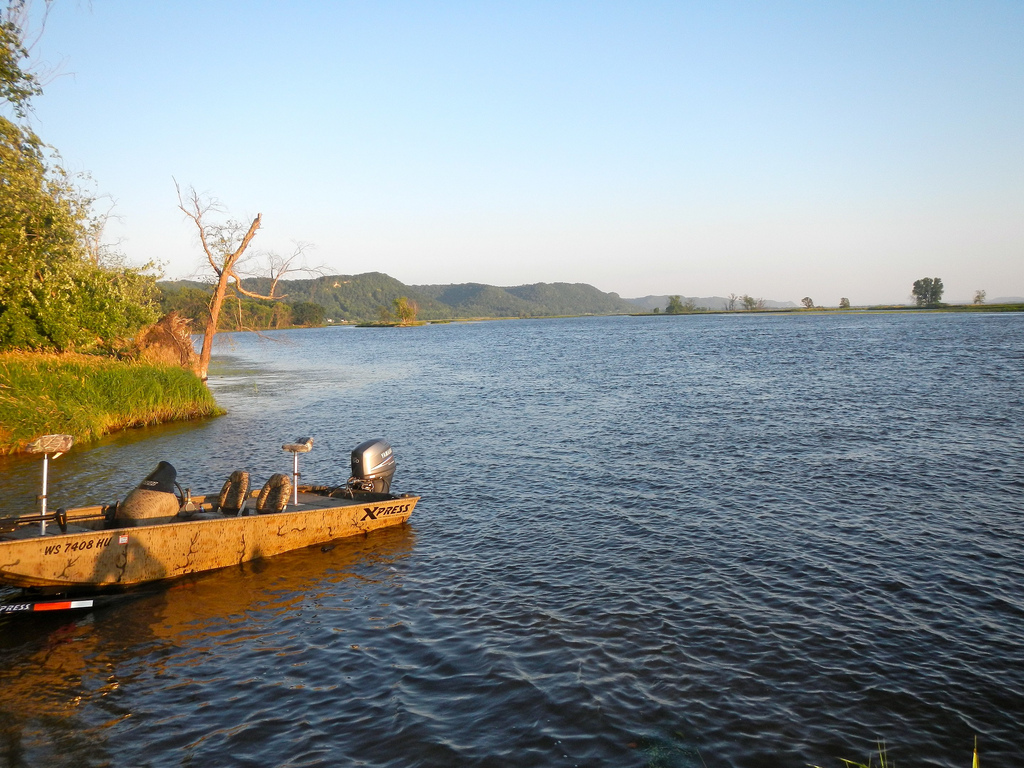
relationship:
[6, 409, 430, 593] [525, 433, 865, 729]
boat on water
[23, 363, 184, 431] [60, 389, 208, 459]
grass growing shoreline